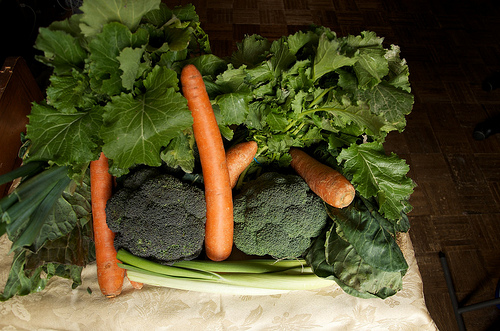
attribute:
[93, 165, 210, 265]
veggie — green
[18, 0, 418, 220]
vegetable — green leaf, piled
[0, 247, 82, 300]
leaf — green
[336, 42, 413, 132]
leaf — piled, green leaf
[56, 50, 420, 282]
vegetable — green leaf, piled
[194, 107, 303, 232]
veggie — orange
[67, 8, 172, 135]
veggie — green, leafy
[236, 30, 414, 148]
leaf — green 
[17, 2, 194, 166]
leaf — green 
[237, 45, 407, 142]
vegetable — green leaf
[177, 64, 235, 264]
veggie — orange